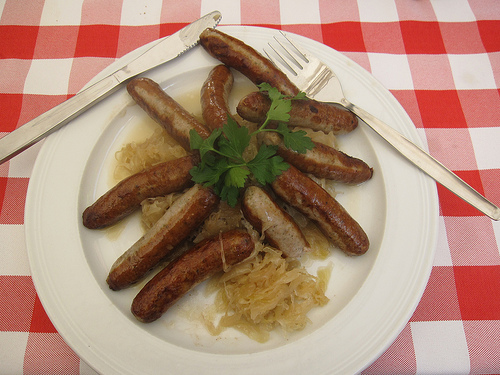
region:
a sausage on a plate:
[270, 157, 371, 256]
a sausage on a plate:
[244, 186, 321, 267]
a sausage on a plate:
[272, 130, 377, 182]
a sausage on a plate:
[242, 87, 363, 139]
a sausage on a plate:
[193, 19, 301, 103]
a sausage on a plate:
[201, 57, 253, 154]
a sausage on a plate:
[129, 75, 216, 154]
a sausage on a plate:
[83, 152, 197, 229]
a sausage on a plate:
[101, 180, 215, 291]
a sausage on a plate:
[132, 227, 251, 321]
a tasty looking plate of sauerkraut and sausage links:
[6, 9, 448, 374]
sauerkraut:
[235, 265, 302, 321]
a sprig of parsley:
[192, 92, 293, 187]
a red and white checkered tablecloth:
[390, 10, 491, 91]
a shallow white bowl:
[370, 170, 425, 276]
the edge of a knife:
[120, 10, 206, 57]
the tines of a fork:
[262, 30, 352, 100]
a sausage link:
[194, 64, 247, 149]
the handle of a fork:
[388, 130, 498, 215]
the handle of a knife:
[36, 87, 115, 129]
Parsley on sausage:
[97, 52, 376, 237]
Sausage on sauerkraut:
[113, 108, 324, 336]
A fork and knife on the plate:
[21, 15, 474, 215]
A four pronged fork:
[235, 14, 432, 171]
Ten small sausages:
[76, 17, 409, 329]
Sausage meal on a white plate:
[31, 22, 449, 372]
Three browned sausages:
[251, 136, 392, 278]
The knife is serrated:
[8, 16, 253, 104]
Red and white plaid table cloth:
[306, 17, 495, 282]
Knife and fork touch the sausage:
[145, 14, 297, 85]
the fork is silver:
[259, 33, 494, 205]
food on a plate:
[16, 19, 435, 374]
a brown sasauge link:
[125, 221, 254, 322]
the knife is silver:
[3, 8, 225, 122]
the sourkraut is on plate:
[222, 263, 332, 331]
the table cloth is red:
[382, 12, 498, 87]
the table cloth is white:
[5, 12, 82, 94]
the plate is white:
[24, 161, 86, 373]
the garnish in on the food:
[183, 131, 300, 193]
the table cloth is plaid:
[432, 288, 485, 368]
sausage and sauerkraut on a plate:
[63, 92, 430, 352]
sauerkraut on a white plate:
[213, 269, 325, 351]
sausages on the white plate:
[86, 193, 234, 309]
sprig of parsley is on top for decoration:
[183, 91, 308, 197]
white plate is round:
[352, 132, 468, 354]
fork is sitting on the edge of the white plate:
[282, 61, 497, 256]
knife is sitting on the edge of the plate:
[0, 18, 209, 139]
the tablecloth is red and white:
[362, 7, 473, 107]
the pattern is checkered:
[378, 11, 470, 111]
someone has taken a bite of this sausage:
[230, 219, 341, 286]